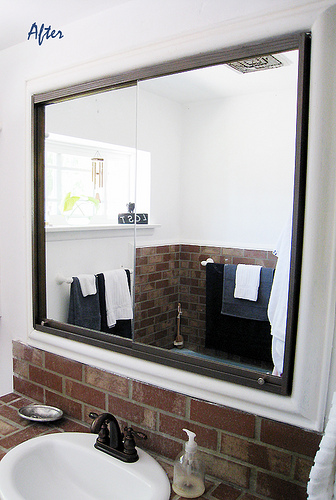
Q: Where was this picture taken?
A: A bathroom.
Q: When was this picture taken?
A: During the day.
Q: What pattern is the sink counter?
A: Bricks.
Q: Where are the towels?
A: On the towel racks.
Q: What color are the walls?
A: White.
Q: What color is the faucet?
A: Brown.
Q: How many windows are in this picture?
A: One.